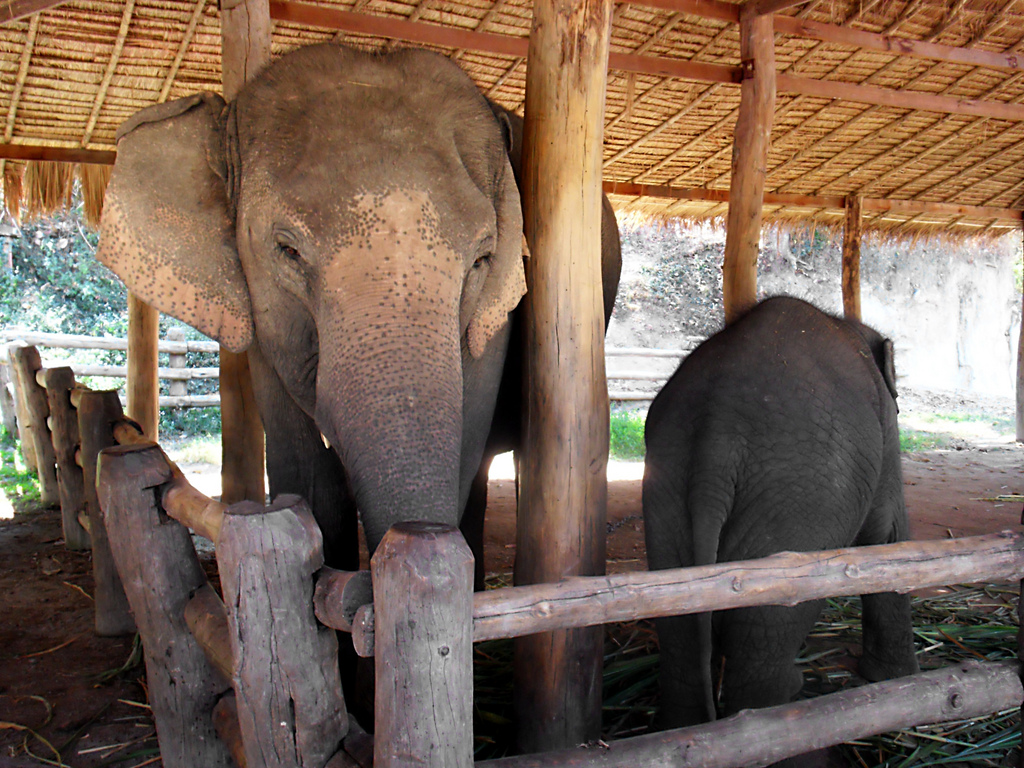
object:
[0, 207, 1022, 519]
beam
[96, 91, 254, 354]
ear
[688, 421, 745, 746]
tail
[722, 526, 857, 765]
legs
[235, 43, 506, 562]
face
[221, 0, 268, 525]
support beam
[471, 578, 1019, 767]
reeds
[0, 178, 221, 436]
vines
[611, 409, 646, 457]
grass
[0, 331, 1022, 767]
fence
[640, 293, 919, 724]
elephant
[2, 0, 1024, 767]
ramada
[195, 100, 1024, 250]
roof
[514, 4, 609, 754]
support beam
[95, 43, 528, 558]
head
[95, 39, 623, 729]
elephant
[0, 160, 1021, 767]
pen